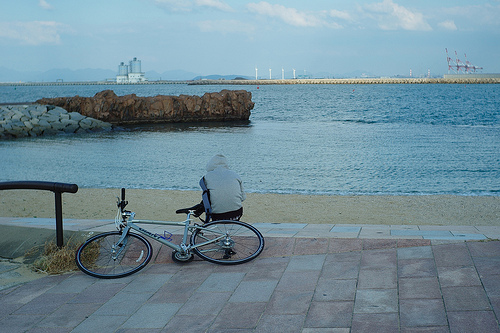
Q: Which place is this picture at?
A: It is at the walkway.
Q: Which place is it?
A: It is a walkway.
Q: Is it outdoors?
A: Yes, it is outdoors.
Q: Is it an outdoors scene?
A: Yes, it is outdoors.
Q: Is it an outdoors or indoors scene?
A: It is outdoors.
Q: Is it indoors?
A: No, it is outdoors.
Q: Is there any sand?
A: Yes, there is sand.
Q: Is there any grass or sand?
A: Yes, there is sand.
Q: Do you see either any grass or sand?
A: Yes, there is sand.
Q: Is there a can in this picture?
A: No, there are no cans.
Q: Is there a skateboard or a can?
A: No, there are no cans or skateboards.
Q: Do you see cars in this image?
A: No, there are no cars.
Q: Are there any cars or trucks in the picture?
A: No, there are no cars or trucks.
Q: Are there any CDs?
A: No, there are no cds.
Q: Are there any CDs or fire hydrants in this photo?
A: No, there are no CDs or fire hydrants.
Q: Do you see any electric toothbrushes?
A: No, there are no electric toothbrushes.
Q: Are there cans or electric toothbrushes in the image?
A: No, there are no electric toothbrushes or cans.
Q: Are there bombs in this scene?
A: No, there are no bombs.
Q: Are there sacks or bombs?
A: No, there are no bombs or sacks.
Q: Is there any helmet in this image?
A: No, there are no helmets.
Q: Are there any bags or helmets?
A: No, there are no helmets or bags.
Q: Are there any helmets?
A: No, there are no helmets.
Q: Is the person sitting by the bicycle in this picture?
A: Yes, the person is sitting by the bicycle.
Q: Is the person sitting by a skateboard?
A: No, the person is sitting by the bicycle.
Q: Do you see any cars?
A: No, there are no cars.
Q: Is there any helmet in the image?
A: No, there are no helmets.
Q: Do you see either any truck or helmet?
A: No, there are no helmets or trucks.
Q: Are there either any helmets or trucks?
A: No, there are no helmets or trucks.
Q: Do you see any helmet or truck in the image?
A: No, there are no helmets or trucks.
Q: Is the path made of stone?
A: Yes, the path is made of stone.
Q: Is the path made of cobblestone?
A: No, the path is made of stone.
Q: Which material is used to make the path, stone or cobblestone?
A: The path is made of stone.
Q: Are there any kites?
A: No, there are no kites.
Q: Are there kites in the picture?
A: No, there are no kites.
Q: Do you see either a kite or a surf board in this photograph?
A: No, there are no kites or surfboards.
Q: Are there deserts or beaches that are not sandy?
A: No, there is a beach but it is sandy.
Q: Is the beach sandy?
A: Yes, the beach is sandy.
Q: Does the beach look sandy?
A: Yes, the beach is sandy.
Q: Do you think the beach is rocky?
A: No, the beach is sandy.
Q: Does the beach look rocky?
A: No, the beach is sandy.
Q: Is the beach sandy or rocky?
A: The beach is sandy.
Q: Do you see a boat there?
A: No, there are no boats.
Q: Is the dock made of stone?
A: Yes, the dock is made of stone.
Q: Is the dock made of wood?
A: No, the dock is made of stone.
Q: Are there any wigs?
A: No, there are no wigs.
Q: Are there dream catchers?
A: No, there are no dream catchers.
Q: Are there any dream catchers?
A: No, there are no dream catchers.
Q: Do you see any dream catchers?
A: No, there are no dream catchers.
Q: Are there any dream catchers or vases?
A: No, there are no dream catchers or vases.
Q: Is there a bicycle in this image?
A: Yes, there is a bicycle.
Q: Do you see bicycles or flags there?
A: Yes, there is a bicycle.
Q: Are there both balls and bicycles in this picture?
A: No, there is a bicycle but no balls.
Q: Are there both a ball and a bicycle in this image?
A: No, there is a bicycle but no balls.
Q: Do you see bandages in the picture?
A: No, there are no bandages.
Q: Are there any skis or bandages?
A: No, there are no bandages or skis.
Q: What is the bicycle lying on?
A: The bicycle is lying on the walkway.